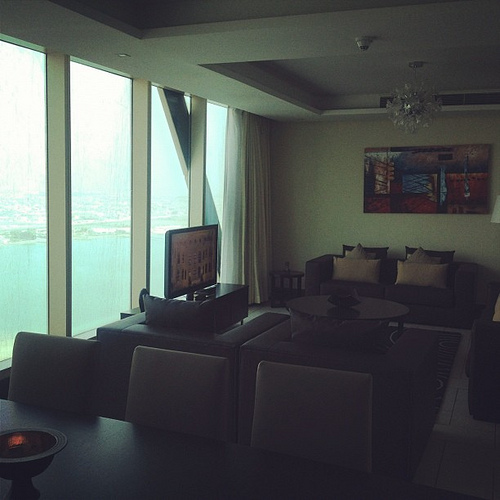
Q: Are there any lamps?
A: No, there are no lamps.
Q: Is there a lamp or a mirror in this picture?
A: No, there are no lamps or mirrors.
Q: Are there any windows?
A: Yes, there is a window.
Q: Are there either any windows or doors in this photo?
A: Yes, there is a window.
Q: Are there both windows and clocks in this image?
A: No, there is a window but no clocks.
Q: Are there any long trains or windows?
A: Yes, there is a long window.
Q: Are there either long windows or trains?
A: Yes, there is a long window.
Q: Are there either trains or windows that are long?
A: Yes, the window is long.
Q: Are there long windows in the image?
A: Yes, there is a long window.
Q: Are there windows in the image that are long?
A: Yes, there is a window that is long.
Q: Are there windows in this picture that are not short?
A: Yes, there is a long window.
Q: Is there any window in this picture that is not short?
A: Yes, there is a long window.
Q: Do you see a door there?
A: No, there are no doors.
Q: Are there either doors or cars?
A: No, there are no doors or cars.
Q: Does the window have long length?
A: Yes, the window is long.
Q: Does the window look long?
A: Yes, the window is long.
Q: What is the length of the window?
A: The window is long.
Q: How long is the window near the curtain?
A: The window is long.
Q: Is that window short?
A: No, the window is long.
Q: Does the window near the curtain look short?
A: No, the window is long.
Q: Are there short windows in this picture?
A: No, there is a window but it is long.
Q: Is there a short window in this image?
A: No, there is a window but it is long.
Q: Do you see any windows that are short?
A: No, there is a window but it is long.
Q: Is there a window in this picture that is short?
A: No, there is a window but it is long.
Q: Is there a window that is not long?
A: No, there is a window but it is long.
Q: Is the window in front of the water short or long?
A: The window is long.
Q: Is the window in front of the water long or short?
A: The window is long.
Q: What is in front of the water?
A: The window is in front of the water.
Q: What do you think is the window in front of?
A: The window is in front of the water.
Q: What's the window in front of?
A: The window is in front of the water.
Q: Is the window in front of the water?
A: Yes, the window is in front of the water.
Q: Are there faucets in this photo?
A: No, there are no faucets.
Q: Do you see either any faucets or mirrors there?
A: No, there are no faucets or mirrors.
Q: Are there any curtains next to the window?
A: Yes, there is a curtain next to the window.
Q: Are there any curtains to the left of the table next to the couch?
A: Yes, there is a curtain to the left of the table.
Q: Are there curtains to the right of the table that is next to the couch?
A: No, the curtain is to the left of the table.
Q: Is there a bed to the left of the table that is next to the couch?
A: No, there is a curtain to the left of the table.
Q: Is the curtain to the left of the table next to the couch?
A: Yes, the curtain is to the left of the table.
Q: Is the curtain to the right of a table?
A: No, the curtain is to the left of a table.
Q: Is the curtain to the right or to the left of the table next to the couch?
A: The curtain is to the left of the table.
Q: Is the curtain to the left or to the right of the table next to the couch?
A: The curtain is to the left of the table.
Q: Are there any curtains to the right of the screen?
A: Yes, there is a curtain to the right of the screen.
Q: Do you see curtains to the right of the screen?
A: Yes, there is a curtain to the right of the screen.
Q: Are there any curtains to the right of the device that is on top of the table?
A: Yes, there is a curtain to the right of the screen.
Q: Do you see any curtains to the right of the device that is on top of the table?
A: Yes, there is a curtain to the right of the screen.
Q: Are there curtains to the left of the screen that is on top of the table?
A: No, the curtain is to the right of the screen.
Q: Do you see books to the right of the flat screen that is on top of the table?
A: No, there is a curtain to the right of the screen.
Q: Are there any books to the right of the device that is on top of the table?
A: No, there is a curtain to the right of the screen.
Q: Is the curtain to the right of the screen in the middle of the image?
A: Yes, the curtain is to the right of the screen.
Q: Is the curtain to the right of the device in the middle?
A: Yes, the curtain is to the right of the screen.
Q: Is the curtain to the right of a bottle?
A: No, the curtain is to the right of the screen.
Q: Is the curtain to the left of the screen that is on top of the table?
A: No, the curtain is to the right of the screen.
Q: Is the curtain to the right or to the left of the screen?
A: The curtain is to the right of the screen.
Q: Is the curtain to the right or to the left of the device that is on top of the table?
A: The curtain is to the right of the screen.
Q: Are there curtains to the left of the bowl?
A: Yes, there is a curtain to the left of the bowl.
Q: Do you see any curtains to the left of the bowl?
A: Yes, there is a curtain to the left of the bowl.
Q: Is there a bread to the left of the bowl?
A: No, there is a curtain to the left of the bowl.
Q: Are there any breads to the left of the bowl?
A: No, there is a curtain to the left of the bowl.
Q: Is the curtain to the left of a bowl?
A: Yes, the curtain is to the left of a bowl.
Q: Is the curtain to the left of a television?
A: No, the curtain is to the left of a bowl.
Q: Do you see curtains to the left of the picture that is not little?
A: Yes, there is a curtain to the left of the picture.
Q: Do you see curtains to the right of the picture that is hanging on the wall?
A: No, the curtain is to the left of the picture.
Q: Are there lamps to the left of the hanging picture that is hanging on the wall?
A: No, there is a curtain to the left of the picture.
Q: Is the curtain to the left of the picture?
A: Yes, the curtain is to the left of the picture.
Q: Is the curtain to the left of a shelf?
A: No, the curtain is to the left of the picture.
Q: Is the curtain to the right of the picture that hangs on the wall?
A: No, the curtain is to the left of the picture.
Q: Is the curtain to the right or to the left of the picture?
A: The curtain is to the left of the picture.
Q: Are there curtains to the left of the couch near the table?
A: Yes, there is a curtain to the left of the couch.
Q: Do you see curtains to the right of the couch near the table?
A: No, the curtain is to the left of the couch.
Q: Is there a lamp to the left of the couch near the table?
A: No, there is a curtain to the left of the couch.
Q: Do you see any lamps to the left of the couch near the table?
A: No, there is a curtain to the left of the couch.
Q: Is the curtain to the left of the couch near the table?
A: Yes, the curtain is to the left of the couch.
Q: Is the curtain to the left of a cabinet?
A: No, the curtain is to the left of the couch.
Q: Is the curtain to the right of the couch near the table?
A: No, the curtain is to the left of the couch.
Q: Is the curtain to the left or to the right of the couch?
A: The curtain is to the left of the couch.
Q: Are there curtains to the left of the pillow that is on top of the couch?
A: Yes, there is a curtain to the left of the pillow.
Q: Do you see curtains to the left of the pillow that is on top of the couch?
A: Yes, there is a curtain to the left of the pillow.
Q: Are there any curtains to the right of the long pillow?
A: No, the curtain is to the left of the pillow.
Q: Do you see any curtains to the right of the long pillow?
A: No, the curtain is to the left of the pillow.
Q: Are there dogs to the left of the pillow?
A: No, there is a curtain to the left of the pillow.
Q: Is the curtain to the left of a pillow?
A: Yes, the curtain is to the left of a pillow.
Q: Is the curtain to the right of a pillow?
A: No, the curtain is to the left of a pillow.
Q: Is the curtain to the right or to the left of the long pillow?
A: The curtain is to the left of the pillow.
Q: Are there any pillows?
A: Yes, there is a pillow.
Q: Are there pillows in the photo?
A: Yes, there is a pillow.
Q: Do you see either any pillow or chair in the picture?
A: Yes, there is a pillow.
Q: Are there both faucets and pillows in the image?
A: No, there is a pillow but no faucets.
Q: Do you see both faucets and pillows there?
A: No, there is a pillow but no faucets.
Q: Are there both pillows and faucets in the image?
A: No, there is a pillow but no faucets.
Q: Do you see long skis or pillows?
A: Yes, there is a long pillow.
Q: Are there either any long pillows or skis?
A: Yes, there is a long pillow.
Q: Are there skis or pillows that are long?
A: Yes, the pillow is long.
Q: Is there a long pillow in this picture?
A: Yes, there is a long pillow.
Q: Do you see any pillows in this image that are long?
A: Yes, there is a pillow that is long.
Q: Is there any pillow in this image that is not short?
A: Yes, there is a long pillow.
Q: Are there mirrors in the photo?
A: No, there are no mirrors.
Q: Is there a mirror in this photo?
A: No, there are no mirrors.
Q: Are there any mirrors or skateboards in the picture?
A: No, there are no mirrors or skateboards.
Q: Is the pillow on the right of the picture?
A: Yes, the pillow is on the right of the image.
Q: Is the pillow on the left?
A: No, the pillow is on the right of the image.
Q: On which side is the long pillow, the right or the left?
A: The pillow is on the right of the image.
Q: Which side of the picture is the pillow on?
A: The pillow is on the right of the image.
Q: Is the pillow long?
A: Yes, the pillow is long.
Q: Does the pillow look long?
A: Yes, the pillow is long.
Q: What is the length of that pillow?
A: The pillow is long.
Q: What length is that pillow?
A: The pillow is long.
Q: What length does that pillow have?
A: The pillow has long length.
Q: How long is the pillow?
A: The pillow is long.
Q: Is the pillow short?
A: No, the pillow is long.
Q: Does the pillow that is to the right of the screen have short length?
A: No, the pillow is long.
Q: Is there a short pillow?
A: No, there is a pillow but it is long.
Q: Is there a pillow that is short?
A: No, there is a pillow but it is long.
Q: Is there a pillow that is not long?
A: No, there is a pillow but it is long.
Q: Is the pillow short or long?
A: The pillow is long.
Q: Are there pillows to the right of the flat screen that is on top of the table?
A: Yes, there is a pillow to the right of the screen.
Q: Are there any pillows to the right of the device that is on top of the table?
A: Yes, there is a pillow to the right of the screen.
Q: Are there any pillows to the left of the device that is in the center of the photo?
A: No, the pillow is to the right of the screen.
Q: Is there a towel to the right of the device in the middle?
A: No, there is a pillow to the right of the screen.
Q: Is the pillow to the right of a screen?
A: Yes, the pillow is to the right of a screen.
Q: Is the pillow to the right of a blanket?
A: No, the pillow is to the right of a screen.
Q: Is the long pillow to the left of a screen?
A: No, the pillow is to the right of a screen.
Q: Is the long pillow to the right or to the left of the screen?
A: The pillow is to the right of the screen.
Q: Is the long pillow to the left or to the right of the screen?
A: The pillow is to the right of the screen.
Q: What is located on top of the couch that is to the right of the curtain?
A: The pillow is on top of the couch.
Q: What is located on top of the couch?
A: The pillow is on top of the couch.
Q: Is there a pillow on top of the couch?
A: Yes, there is a pillow on top of the couch.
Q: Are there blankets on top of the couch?
A: No, there is a pillow on top of the couch.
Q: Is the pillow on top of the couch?
A: Yes, the pillow is on top of the couch.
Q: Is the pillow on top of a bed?
A: No, the pillow is on top of the couch.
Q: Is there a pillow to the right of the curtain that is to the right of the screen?
A: Yes, there is a pillow to the right of the curtain.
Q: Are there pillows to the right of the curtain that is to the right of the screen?
A: Yes, there is a pillow to the right of the curtain.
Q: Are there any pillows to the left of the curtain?
A: No, the pillow is to the right of the curtain.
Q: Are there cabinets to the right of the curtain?
A: No, there is a pillow to the right of the curtain.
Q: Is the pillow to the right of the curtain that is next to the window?
A: Yes, the pillow is to the right of the curtain.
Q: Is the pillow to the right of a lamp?
A: No, the pillow is to the right of the curtain.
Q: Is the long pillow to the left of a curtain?
A: No, the pillow is to the right of a curtain.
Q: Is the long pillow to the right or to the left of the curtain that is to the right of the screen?
A: The pillow is to the right of the curtain.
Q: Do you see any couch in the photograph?
A: Yes, there is a couch.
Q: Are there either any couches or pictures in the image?
A: Yes, there is a couch.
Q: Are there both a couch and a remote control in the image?
A: No, there is a couch but no remote controls.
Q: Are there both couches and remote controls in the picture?
A: No, there is a couch but no remote controls.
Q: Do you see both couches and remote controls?
A: No, there is a couch but no remote controls.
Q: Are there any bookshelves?
A: No, there are no bookshelves.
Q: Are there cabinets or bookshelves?
A: No, there are no bookshelves or cabinets.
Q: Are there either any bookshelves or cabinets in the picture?
A: No, there are no bookshelves or cabinets.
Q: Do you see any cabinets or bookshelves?
A: No, there are no bookshelves or cabinets.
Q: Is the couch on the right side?
A: Yes, the couch is on the right of the image.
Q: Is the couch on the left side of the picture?
A: No, the couch is on the right of the image.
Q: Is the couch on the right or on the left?
A: The couch is on the right of the image.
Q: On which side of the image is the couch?
A: The couch is on the right of the image.